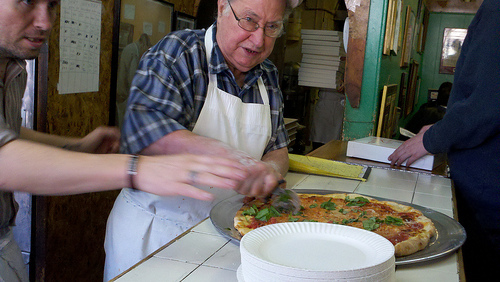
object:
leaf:
[383, 216, 403, 225]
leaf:
[320, 198, 334, 210]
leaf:
[254, 205, 274, 223]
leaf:
[241, 205, 258, 216]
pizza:
[232, 193, 438, 257]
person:
[101, 0, 303, 282]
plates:
[240, 220, 396, 279]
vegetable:
[308, 204, 316, 209]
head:
[215, 0, 300, 72]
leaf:
[363, 216, 380, 231]